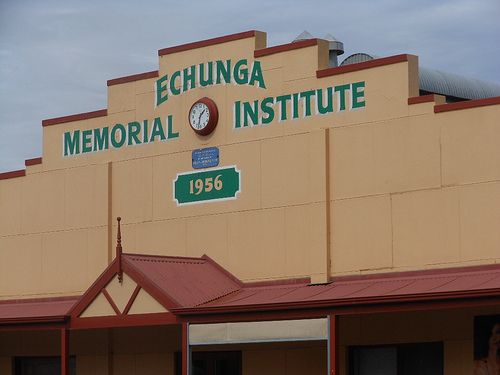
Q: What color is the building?
A: Brown.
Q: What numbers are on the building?
A: 1956.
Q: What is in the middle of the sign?
A: Clock.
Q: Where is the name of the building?
A: Front.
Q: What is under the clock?
A: Blue sign.